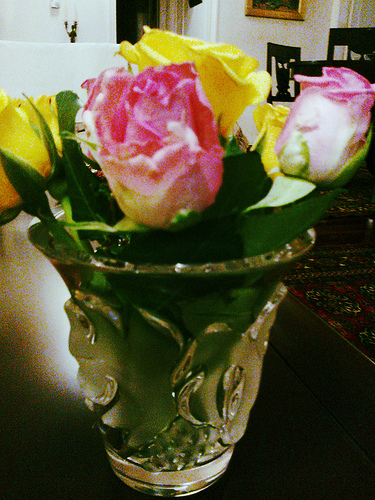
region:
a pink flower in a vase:
[73, 62, 228, 230]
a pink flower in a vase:
[278, 65, 373, 186]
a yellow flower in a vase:
[251, 104, 294, 176]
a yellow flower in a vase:
[119, 25, 272, 139]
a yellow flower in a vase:
[10, 90, 76, 154]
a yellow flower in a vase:
[1, 90, 57, 220]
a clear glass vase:
[24, 221, 333, 489]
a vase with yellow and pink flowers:
[4, 26, 357, 497]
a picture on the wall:
[239, 0, 304, 22]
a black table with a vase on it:
[1, 202, 373, 498]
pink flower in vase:
[96, 78, 221, 231]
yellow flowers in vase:
[30, 74, 261, 196]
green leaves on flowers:
[32, 92, 307, 233]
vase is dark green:
[70, 211, 290, 484]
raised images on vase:
[70, 300, 253, 469]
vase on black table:
[13, 204, 248, 466]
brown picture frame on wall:
[240, 0, 315, 25]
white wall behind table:
[22, 14, 105, 41]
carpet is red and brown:
[298, 226, 373, 352]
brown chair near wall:
[316, 21, 364, 67]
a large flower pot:
[24, 224, 318, 494]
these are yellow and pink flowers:
[1, 24, 373, 262]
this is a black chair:
[264, 39, 302, 106]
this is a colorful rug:
[277, 191, 373, 365]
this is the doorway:
[116, 0, 159, 46]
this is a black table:
[294, 59, 374, 83]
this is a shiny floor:
[2, 189, 373, 498]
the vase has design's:
[26, 203, 316, 498]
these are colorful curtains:
[156, 0, 189, 36]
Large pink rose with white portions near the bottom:
[76, 72, 215, 222]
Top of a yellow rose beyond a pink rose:
[133, 21, 263, 139]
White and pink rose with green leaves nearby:
[277, 62, 367, 180]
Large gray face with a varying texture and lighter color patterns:
[28, 225, 306, 498]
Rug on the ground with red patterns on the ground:
[290, 267, 373, 345]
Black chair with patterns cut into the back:
[260, 33, 304, 107]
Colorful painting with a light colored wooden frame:
[246, 0, 308, 23]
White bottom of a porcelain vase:
[99, 442, 251, 497]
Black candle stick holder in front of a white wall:
[62, 16, 82, 41]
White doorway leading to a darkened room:
[114, 2, 209, 37]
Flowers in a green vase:
[0, 23, 374, 497]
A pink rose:
[74, 58, 245, 238]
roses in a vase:
[1, 30, 373, 495]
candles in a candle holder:
[59, 2, 85, 44]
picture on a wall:
[241, 0, 311, 23]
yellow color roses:
[0, 84, 68, 220]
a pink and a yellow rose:
[75, 21, 270, 223]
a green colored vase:
[24, 214, 314, 492]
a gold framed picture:
[240, 0, 310, 23]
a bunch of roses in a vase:
[1, 28, 370, 497]